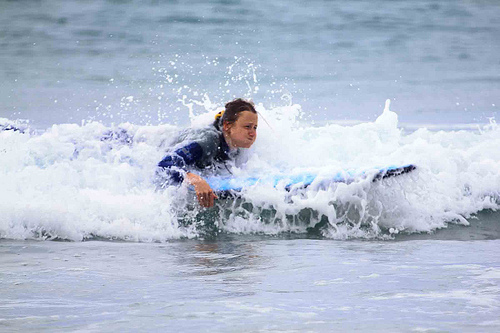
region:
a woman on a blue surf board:
[117, 99, 419, 214]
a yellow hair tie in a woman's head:
[209, 108, 229, 123]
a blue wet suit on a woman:
[155, 123, 260, 191]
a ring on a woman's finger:
[197, 192, 207, 207]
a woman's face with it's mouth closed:
[222, 102, 264, 148]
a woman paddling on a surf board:
[110, 99, 415, 198]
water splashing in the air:
[118, 37, 317, 132]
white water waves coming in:
[6, 105, 486, 239]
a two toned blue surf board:
[201, 160, 421, 192]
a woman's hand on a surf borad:
[178, 172, 215, 208]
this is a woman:
[134, 76, 299, 230]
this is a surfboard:
[155, 157, 425, 236]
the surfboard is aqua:
[155, 151, 435, 221]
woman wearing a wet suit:
[120, 110, 220, 198]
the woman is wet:
[83, 50, 277, 207]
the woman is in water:
[50, 41, 337, 224]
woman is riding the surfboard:
[28, 61, 428, 264]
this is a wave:
[35, 71, 499, 239]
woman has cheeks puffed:
[222, 107, 274, 158]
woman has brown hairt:
[200, 87, 262, 129]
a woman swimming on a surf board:
[78, 96, 422, 215]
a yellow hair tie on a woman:
[211, 105, 229, 130]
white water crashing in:
[9, 114, 498, 231]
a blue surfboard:
[156, 162, 423, 194]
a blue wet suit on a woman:
[146, 119, 251, 208]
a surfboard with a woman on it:
[181, 162, 414, 203]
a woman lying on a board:
[121, 92, 288, 227]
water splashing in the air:
[129, 44, 300, 124]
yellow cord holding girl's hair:
[212, 107, 226, 119]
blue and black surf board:
[174, 160, 415, 200]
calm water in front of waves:
[0, 233, 497, 332]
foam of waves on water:
[2, 107, 497, 249]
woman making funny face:
[2, 89, 260, 210]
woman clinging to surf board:
[0, 91, 263, 214]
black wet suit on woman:
[155, 125, 240, 185]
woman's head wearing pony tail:
[210, 95, 264, 152]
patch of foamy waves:
[11, 181, 88, 236]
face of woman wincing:
[239, 115, 260, 142]